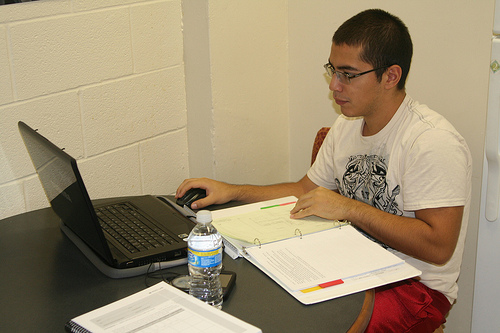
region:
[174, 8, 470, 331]
Man working at table.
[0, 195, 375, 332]
Round, black table with brown border.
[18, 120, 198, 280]
Black laptop computer on table.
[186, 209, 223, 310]
Plastic bottle of water with blue label.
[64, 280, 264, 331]
Spiral-bound book on table.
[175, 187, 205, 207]
Black computer mouse in man's hand.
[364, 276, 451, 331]
Red pair of shorts on man.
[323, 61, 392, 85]
Pair of glasses with black frame.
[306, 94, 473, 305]
White t-shirt with black print.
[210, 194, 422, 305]
Open three-ring notebook on table.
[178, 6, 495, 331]
man sitting at table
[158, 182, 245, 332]
water bottle on table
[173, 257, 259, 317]
black cell phone on table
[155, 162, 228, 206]
black mouse on table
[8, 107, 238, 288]
black lap top on table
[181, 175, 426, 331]
booklet on table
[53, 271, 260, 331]
binding booklet on table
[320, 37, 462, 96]
man wearing glasses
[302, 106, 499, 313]
man wearing white shirt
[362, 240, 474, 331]
man wearing red shorts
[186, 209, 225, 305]
Plastic bottle of water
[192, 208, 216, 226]
Plastic water bottle cap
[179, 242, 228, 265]
Label on plastic water bottle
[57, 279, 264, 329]
Stack of spiral bound books on table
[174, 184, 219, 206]
Electronic computer mouse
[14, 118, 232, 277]
Open laptop on table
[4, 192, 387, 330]
Round table trimmed in wood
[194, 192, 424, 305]
Open three ring notebook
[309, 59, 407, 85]
Eyeglasses on man's face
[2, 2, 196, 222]
Wall made of cinderblock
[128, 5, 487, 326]
man sitting at table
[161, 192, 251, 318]
bottle of water on table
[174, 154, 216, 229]
black mouse on table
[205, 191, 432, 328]
booklet on table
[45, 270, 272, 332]
booklets on the table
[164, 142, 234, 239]
black mouse on table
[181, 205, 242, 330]
bottled water on table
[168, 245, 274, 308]
black cellphone on the table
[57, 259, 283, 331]
booklet on the table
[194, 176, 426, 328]
booklet on the table